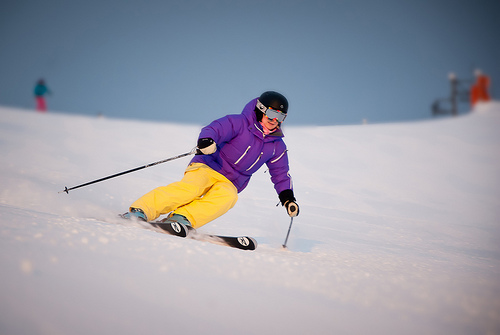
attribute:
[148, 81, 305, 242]
person — skiing, leaning, colorful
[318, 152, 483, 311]
snow — white, whiter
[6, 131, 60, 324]
snow — white, blueish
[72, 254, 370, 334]
snow — white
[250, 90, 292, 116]
helmet — black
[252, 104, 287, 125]
goggles — gray, grey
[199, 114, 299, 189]
coat — purple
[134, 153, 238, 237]
pants — yellow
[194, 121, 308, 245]
leaning — black, white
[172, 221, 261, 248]
ski — left ski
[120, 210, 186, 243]
ski — right ski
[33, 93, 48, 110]
pants — pink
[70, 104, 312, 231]
skier — leaning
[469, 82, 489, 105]
pants — red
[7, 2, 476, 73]
sky — blue, clear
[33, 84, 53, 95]
coat — blue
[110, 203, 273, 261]
skis — black, white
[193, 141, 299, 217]
hands — gloved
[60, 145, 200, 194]
ski pole — right ski pole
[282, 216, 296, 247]
ski pole — left ski pole